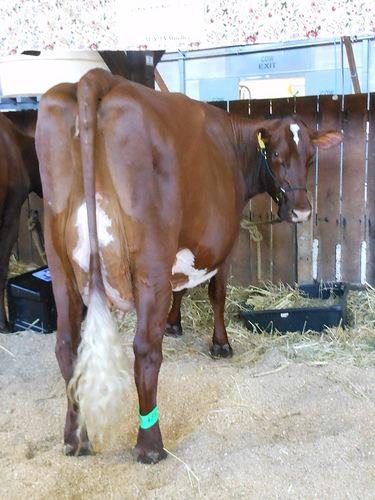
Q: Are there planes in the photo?
A: No, there are no planes.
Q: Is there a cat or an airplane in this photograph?
A: No, there are no airplanes or cats.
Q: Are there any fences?
A: Yes, there is a fence.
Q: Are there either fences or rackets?
A: Yes, there is a fence.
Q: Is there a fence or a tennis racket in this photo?
A: Yes, there is a fence.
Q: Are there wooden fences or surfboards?
A: Yes, there is a wood fence.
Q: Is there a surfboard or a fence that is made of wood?
A: Yes, the fence is made of wood.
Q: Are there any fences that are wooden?
A: Yes, there is a wood fence.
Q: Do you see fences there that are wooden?
A: Yes, there is a fence that is wooden.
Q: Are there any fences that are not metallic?
A: Yes, there is a wooden fence.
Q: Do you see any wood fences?
A: Yes, there is a fence that is made of wood.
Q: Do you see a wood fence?
A: Yes, there is a fence that is made of wood.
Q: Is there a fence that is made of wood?
A: Yes, there is a fence that is made of wood.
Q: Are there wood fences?
A: Yes, there is a fence that is made of wood.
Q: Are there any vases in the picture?
A: No, there are no vases.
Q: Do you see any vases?
A: No, there are no vases.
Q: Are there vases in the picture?
A: No, there are no vases.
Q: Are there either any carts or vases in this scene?
A: No, there are no vases or carts.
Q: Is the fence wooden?
A: Yes, the fence is wooden.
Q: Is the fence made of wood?
A: Yes, the fence is made of wood.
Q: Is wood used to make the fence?
A: Yes, the fence is made of wood.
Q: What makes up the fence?
A: The fence is made of wood.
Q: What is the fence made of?
A: The fence is made of wood.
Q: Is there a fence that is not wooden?
A: No, there is a fence but it is wooden.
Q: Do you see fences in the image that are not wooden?
A: No, there is a fence but it is wooden.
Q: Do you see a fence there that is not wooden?
A: No, there is a fence but it is wooden.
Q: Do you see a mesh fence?
A: No, there is a fence but it is made of wood.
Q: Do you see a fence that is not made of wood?
A: No, there is a fence but it is made of wood.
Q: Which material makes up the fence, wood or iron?
A: The fence is made of wood.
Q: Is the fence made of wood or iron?
A: The fence is made of wood.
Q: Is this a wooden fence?
A: Yes, this is a wooden fence.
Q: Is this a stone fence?
A: No, this is a wooden fence.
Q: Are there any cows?
A: Yes, there is a cow.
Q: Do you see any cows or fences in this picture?
A: Yes, there is a cow.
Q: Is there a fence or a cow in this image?
A: Yes, there is a cow.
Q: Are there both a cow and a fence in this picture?
A: Yes, there are both a cow and a fence.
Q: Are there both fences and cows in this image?
A: Yes, there are both a cow and a fence.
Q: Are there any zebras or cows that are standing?
A: Yes, the cow is standing.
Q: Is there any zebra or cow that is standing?
A: Yes, the cow is standing.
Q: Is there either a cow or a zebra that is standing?
A: Yes, the cow is standing.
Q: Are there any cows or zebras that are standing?
A: Yes, the cow is standing.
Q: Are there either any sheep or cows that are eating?
A: Yes, the cow is eating.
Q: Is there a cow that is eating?
A: Yes, there is a cow that is eating.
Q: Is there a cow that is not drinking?
A: Yes, there is a cow that is eating.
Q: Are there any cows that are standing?
A: Yes, there is a cow that is standing.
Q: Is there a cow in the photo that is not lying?
A: Yes, there is a cow that is standing.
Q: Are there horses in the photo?
A: No, there are no horses.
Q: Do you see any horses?
A: No, there are no horses.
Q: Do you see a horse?
A: No, there are no horses.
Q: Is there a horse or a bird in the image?
A: No, there are no horses or birds.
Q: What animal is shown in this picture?
A: The animal is a cow.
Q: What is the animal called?
A: The animal is a cow.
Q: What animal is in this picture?
A: The animal is a cow.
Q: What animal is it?
A: The animal is a cow.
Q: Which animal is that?
A: This is a cow.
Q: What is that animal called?
A: This is a cow.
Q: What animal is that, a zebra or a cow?
A: This is a cow.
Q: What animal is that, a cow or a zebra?
A: This is a cow.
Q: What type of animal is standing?
A: The animal is a cow.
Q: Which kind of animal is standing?
A: The animal is a cow.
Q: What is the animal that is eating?
A: The animal is a cow.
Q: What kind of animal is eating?
A: The animal is a cow.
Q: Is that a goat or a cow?
A: That is a cow.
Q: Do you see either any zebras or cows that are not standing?
A: No, there is a cow but it is standing.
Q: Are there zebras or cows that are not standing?
A: No, there is a cow but it is standing.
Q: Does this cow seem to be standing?
A: Yes, the cow is standing.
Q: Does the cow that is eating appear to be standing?
A: Yes, the cow is standing.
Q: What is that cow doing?
A: The cow is standing.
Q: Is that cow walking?
A: No, the cow is standing.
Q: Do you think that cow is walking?
A: No, the cow is standing.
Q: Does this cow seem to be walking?
A: No, the cow is standing.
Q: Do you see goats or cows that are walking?
A: No, there is a cow but it is standing.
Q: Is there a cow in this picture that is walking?
A: No, there is a cow but it is standing.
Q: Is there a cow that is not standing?
A: No, there is a cow but it is standing.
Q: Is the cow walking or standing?
A: The cow is standing.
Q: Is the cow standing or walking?
A: The cow is standing.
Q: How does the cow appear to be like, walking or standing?
A: The cow is standing.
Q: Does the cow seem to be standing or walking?
A: The cow is standing.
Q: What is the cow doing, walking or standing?
A: The cow is standing.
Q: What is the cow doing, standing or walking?
A: The cow is standing.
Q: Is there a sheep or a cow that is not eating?
A: No, there is a cow but it is eating.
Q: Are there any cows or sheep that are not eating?
A: No, there is a cow but it is eating.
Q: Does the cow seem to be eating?
A: Yes, the cow is eating.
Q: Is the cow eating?
A: Yes, the cow is eating.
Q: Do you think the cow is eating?
A: Yes, the cow is eating.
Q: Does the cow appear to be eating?
A: Yes, the cow is eating.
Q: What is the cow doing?
A: The cow is eating.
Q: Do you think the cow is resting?
A: No, the cow is eating.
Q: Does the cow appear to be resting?
A: No, the cow is eating.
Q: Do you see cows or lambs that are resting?
A: No, there is a cow but it is eating.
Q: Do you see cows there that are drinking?
A: No, there is a cow but it is eating.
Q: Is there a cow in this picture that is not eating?
A: No, there is a cow but it is eating.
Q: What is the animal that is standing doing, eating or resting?
A: The cow is eating.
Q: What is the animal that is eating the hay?
A: The animal is a cow.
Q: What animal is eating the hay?
A: The animal is a cow.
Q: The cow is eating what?
A: The cow is eating hay.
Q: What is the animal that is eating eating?
A: The cow is eating hay.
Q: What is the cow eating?
A: The cow is eating hay.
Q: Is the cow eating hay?
A: Yes, the cow is eating hay.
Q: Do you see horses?
A: No, there are no horses.